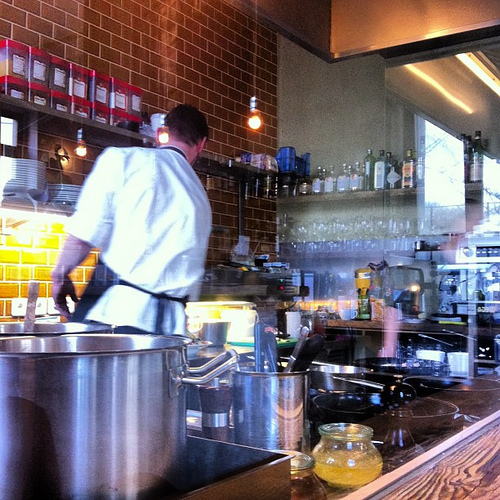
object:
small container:
[186, 361, 308, 468]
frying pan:
[310, 385, 387, 420]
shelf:
[4, 94, 300, 185]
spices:
[0, 33, 143, 133]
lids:
[0, 35, 141, 131]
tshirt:
[69, 139, 211, 343]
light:
[246, 35, 263, 135]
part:
[468, 400, 484, 421]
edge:
[392, 445, 437, 473]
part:
[412, 377, 432, 391]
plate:
[406, 374, 499, 407]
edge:
[263, 410, 279, 426]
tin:
[231, 366, 309, 469]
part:
[248, 465, 283, 484]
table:
[165, 368, 500, 500]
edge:
[461, 423, 480, 439]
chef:
[0, 97, 276, 241]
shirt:
[67, 143, 223, 340]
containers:
[0, 35, 150, 135]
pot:
[0, 334, 198, 499]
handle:
[176, 348, 239, 386]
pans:
[312, 385, 390, 423]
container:
[305, 417, 382, 490]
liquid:
[313, 451, 385, 487]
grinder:
[378, 366, 419, 460]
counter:
[172, 350, 499, 494]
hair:
[161, 102, 211, 147]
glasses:
[281, 212, 432, 260]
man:
[50, 103, 214, 349]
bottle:
[296, 146, 415, 196]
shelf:
[295, 175, 432, 203]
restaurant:
[0, 0, 499, 499]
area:
[0, 0, 499, 499]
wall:
[279, 34, 430, 260]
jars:
[336, 162, 355, 196]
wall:
[0, 0, 280, 329]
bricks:
[143, 6, 287, 87]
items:
[242, 300, 455, 456]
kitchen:
[0, 1, 499, 499]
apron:
[67, 259, 189, 321]